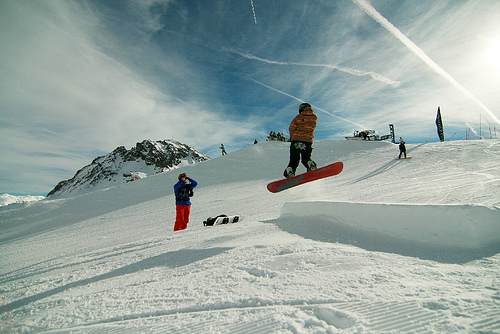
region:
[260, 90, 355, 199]
person doing a snowboard jump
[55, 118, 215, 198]
snow covered mountain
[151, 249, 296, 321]
snow covering the ground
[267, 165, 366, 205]
long red snowboard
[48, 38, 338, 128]
clouds covering the sky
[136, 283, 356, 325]
tracks made in the snow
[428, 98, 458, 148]
black flag stuck into snow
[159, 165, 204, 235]
person watching snowboarder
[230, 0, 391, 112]
white lines in sky from airplanes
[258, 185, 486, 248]
snowboard jump made of snow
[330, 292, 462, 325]
straight lines on the snow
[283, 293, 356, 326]
large foot print in the white snow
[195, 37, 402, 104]
white streaks across the sky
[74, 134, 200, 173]
snow covered mountain range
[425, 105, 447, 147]
large flag on top of hill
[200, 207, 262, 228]
black and white bag on the snow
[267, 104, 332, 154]
brown jacket with red lines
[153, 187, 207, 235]
man's red pants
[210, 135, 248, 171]
skier skiing down hill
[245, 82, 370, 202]
skier doing tricks on snow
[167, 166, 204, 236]
Person taking a picture of another snowboarder.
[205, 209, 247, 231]
Black and white snowboard lying in the snow.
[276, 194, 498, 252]
Snow packed tightly to create a jump.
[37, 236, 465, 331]
Ground covered in snow on the mountainside.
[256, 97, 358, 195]
Snowboarder jumping on the man made jump.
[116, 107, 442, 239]
Several people snowboarding on the mountain.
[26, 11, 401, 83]
Blue sky filled with thin clouds.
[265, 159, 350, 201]
Red snowboard.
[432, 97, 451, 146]
Tall black flag sticking out of the snow.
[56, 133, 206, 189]
Rocky mountain in the distance with snow on it.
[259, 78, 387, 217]
Snow boarder in the air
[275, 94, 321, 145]
Jacket on a snowboarder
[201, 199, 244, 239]
Snowboard on the ground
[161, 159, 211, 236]
Person standing in snow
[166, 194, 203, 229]
Red pants on a person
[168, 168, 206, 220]
Blue jacket on a person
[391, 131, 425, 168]
Person snowboarding down a hill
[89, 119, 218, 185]
Snow covered rock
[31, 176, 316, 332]
White snow covered hill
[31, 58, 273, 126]
Blue and white cloudy sky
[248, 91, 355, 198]
Girl is on snowboard.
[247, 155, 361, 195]
The snowboard is red.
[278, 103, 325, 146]
The girl is wearing a coat.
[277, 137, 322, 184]
The girl is wearing snowpants.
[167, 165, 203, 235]
An individual taking pictures.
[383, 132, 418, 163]
A person is snowboarding.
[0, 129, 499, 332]
The snow is white.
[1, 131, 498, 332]
The ground is covered in snow.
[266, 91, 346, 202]
The snowboarder is airborne.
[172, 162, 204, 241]
A person is standing in the snow.